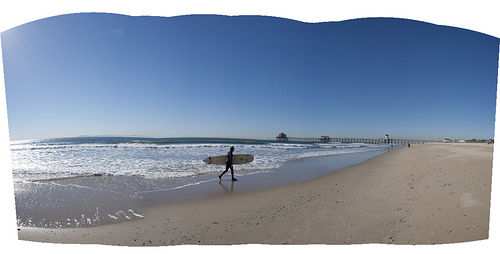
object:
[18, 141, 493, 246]
beach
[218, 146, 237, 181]
man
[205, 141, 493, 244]
beach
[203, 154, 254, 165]
surfboard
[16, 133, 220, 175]
ocean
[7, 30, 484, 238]
day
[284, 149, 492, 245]
edge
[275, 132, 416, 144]
pier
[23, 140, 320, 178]
waves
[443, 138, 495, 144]
houses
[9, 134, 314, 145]
horizon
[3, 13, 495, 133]
skies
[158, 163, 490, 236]
shore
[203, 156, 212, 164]
tip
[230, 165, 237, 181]
legs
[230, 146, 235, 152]
head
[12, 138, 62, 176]
reflection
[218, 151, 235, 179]
wet suit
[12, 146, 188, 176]
white foam